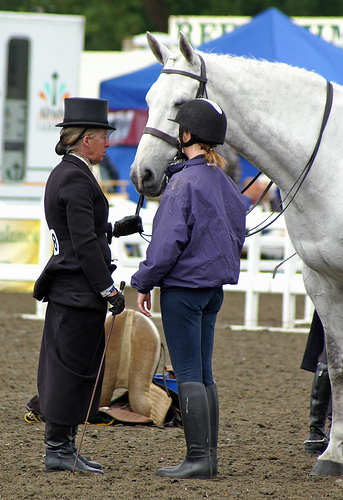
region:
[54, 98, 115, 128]
woman wearing a black top hat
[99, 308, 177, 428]
a horse saddle on the ground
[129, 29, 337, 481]
a white horse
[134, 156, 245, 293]
woman wearing a purple windbreaker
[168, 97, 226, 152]
woman wearing a black helmet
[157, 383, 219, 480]
woman wearing black knee high boots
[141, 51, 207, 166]
horse wearing a leather harness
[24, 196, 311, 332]
white wooden hedges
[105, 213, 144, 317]
woman wearing black leather gloves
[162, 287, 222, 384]
woman wearing blue fitted jeans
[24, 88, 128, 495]
This is a woman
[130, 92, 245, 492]
This is a woman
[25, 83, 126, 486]
This is a woman in boots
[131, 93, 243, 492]
This is a woman in boots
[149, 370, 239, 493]
These are black boots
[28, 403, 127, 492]
These are black boots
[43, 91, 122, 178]
Head of a person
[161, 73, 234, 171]
Head of a person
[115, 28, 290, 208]
Head of a horse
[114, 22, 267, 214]
Head of a white horse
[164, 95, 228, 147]
Black and white helmet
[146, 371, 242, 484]
Black boots on woman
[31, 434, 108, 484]
Black shoes on person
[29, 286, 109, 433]
Black skirt on person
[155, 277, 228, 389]
Blue jeans on woman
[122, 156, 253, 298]
Purple jacket on woman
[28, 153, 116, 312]
Black jacket on person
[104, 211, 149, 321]
Black gloves on person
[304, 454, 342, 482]
Hoof on white horse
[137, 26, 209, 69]
Ears on white horse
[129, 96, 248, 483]
An equestrian standing by a horse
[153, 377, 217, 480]
The boots of the equestrian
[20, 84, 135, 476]
The woman has on a black garment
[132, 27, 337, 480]
A white horse standing in the field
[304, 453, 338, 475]
The shoe of the horse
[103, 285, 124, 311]
The woman is wearing a glove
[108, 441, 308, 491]
The dirt is brown and soft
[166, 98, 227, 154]
The helmet on the rider is black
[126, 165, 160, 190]
The nose of the horse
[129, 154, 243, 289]
The rider is wearing a purple jacket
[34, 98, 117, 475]
woman holding a riding crop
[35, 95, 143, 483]
woman holding the horse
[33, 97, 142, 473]
woman wearing a top hat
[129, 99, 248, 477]
woman wearing a purple coat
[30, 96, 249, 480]
two women standing next to the horse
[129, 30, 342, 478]
large white horse next to the women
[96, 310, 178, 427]
saddle on the ground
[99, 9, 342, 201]
blue tend on the other side of the fence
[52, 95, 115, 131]
black top hat on the woman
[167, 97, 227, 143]
black and white helmet